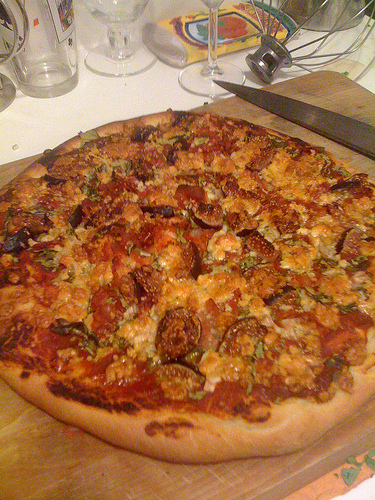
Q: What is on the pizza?
A: Pepperoni.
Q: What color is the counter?
A: Brown.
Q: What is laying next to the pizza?
A: Knife.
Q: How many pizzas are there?
A: One.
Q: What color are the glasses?
A: Clear.